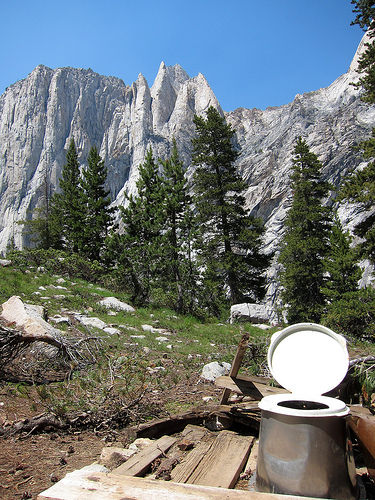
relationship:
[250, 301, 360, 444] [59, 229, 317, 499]
toilet in field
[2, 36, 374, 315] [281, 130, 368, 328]
mountain with pine tree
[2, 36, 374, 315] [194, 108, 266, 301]
mountain with pine tree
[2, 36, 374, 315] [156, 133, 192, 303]
mountain with pine tree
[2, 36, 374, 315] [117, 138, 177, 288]
mountain with pine tree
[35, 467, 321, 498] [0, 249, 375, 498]
board on ground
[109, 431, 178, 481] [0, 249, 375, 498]
board on ground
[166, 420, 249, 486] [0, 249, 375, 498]
board on ground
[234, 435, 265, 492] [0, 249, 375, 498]
board on ground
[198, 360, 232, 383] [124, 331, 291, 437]
rock behind wood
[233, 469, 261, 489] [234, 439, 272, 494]
water on wood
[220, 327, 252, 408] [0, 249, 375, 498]
wood piece on ground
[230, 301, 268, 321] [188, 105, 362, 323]
rock in front of trees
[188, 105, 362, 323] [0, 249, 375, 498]
trees on ground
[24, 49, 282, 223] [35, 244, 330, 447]
rocks on ground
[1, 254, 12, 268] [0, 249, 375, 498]
white rock on ground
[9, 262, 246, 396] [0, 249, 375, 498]
rocks on ground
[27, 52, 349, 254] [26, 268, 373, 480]
rocks on ground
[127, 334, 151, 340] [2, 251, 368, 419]
rock on ground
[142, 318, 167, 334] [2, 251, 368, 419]
rock on ground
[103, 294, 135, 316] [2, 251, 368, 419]
rock on ground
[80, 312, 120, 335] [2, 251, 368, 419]
rock on ground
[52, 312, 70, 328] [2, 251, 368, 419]
rock on ground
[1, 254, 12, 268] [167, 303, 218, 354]
white rock on ground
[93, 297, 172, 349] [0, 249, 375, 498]
rocks on ground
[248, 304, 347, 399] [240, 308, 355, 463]
cover on toilet